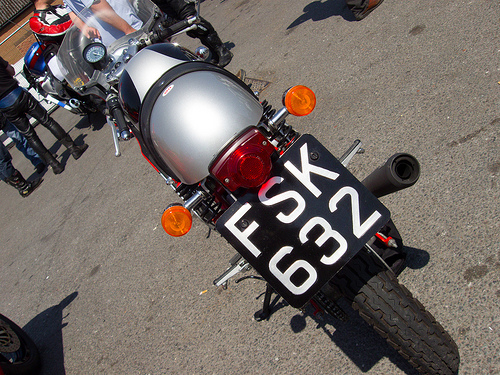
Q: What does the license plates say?
A: It says fsk632.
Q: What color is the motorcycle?
A: It is silver and black.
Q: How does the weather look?
A: The weather looks nice and sunny.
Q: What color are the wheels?
A: The wheels are black.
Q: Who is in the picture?
A: A few people are in the picture.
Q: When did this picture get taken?
A: It was taken in the day time.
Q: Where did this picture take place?
A: It took place at a bike event.